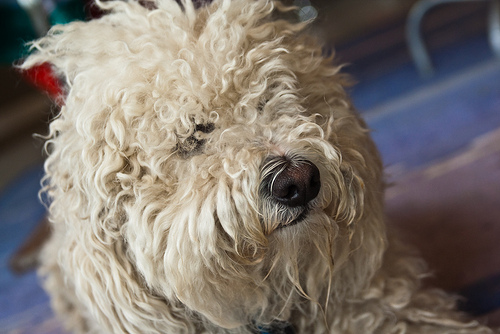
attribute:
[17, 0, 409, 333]
dog — white, furry, sitting, fuzzy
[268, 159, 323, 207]
nose — black, small, hairy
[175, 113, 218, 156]
eye — black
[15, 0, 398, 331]
head — white, furry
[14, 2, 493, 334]
fur — curly, long, white, crimped, scraggly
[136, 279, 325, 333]
collar — black, hidden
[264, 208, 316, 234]
mouth — black, small, covered, hairy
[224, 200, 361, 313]
fur — wet, dirty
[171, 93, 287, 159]
eyes — hidden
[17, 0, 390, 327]
fur — white, tuft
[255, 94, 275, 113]
eye — black, hidden, covered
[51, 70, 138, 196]
ear — furry, floppy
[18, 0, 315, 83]
fur — sticking, lone, tuft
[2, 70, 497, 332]
carpet — blue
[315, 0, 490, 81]
table — wooden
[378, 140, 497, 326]
rug — red